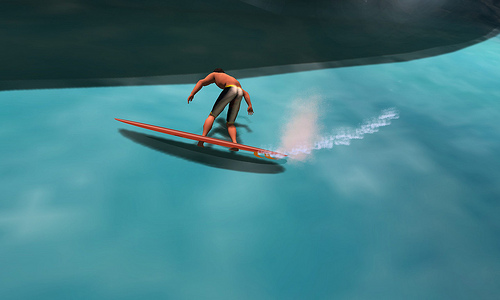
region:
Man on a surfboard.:
[70, 24, 410, 211]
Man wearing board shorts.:
[177, 39, 331, 187]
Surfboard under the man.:
[107, 101, 301, 196]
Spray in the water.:
[278, 102, 448, 186]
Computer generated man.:
[125, 23, 310, 204]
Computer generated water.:
[266, 65, 467, 254]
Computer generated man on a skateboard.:
[98, 38, 409, 212]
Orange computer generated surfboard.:
[102, 104, 334, 177]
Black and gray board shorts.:
[178, 77, 276, 129]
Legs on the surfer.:
[190, 107, 300, 187]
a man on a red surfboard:
[122, 74, 282, 166]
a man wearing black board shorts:
[182, 47, 258, 147]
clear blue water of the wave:
[51, 170, 457, 286]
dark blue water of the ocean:
[13, 12, 423, 70]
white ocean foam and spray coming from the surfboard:
[267, 120, 401, 185]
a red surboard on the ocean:
[83, 118, 280, 171]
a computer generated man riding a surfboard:
[106, 51, 290, 175]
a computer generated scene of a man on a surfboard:
[4, 14, 486, 291]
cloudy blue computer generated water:
[23, 165, 479, 289]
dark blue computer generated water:
[24, 8, 424, 83]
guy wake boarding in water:
[113, 65, 305, 189]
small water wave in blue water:
[305, 97, 412, 185]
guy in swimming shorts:
[187, 63, 264, 163]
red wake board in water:
[107, 108, 289, 173]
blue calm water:
[51, 172, 159, 254]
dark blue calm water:
[36, 5, 141, 60]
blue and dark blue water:
[315, 15, 442, 110]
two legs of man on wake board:
[190, 122, 240, 162]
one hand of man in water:
[173, 75, 205, 108]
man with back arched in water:
[181, 68, 271, 118]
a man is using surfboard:
[108, 58, 363, 183]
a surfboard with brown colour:
[106, 116, 301, 165]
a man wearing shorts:
[207, 81, 248, 161]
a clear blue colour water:
[105, 197, 411, 266]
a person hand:
[186, 68, 205, 106]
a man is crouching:
[188, 58, 259, 140]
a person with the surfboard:
[106, 62, 301, 182]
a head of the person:
[211, 63, 227, 76]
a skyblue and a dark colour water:
[11, 11, 83, 172]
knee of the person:
[199, 105, 250, 132]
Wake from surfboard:
[321, 100, 401, 155]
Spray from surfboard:
[273, 91, 336, 174]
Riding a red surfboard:
[114, 103, 288, 165]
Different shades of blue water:
[331, 41, 497, 290]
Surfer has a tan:
[186, 64, 258, 115]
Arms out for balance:
[179, 65, 261, 115]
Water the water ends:
[11, 32, 491, 108]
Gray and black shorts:
[204, 80, 249, 133]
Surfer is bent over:
[177, 61, 263, 151]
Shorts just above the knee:
[194, 107, 246, 129]